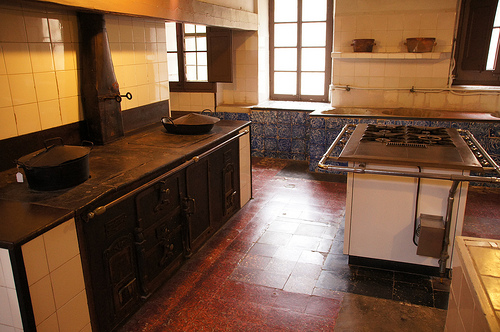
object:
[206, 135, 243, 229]
cabinet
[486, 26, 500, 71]
window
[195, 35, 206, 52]
window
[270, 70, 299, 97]
pane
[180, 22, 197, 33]
pane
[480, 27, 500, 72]
pane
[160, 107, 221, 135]
skillet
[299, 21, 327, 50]
window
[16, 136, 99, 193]
skillet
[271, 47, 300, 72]
window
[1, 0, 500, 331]
room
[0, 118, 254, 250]
counter